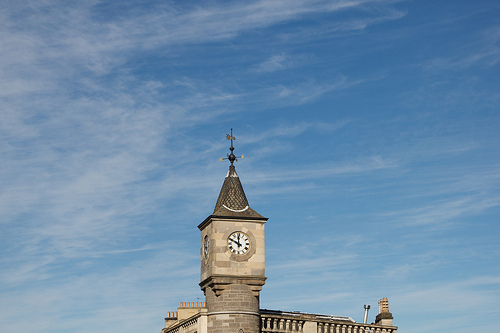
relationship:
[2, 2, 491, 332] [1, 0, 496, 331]
clouds in sky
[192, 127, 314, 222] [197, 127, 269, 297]
vane on steeple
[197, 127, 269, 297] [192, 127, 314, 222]
steeple has vane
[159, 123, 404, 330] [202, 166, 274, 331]
building with tower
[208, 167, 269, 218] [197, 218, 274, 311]
pointed roof for clock tower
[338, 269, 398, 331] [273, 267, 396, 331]
object from roof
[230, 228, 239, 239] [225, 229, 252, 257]
numeral on clock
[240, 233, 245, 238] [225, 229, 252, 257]
numeral on clock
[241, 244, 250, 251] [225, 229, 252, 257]
numeral on clock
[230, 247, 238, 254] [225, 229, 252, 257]
numeral on clock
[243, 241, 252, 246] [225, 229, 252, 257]
numeral on clock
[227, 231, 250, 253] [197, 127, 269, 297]
clock on steeple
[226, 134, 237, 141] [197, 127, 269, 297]
vane on top of steeple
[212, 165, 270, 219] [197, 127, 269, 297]
pointed roof on top of steeple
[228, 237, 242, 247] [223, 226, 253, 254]
black hand on clock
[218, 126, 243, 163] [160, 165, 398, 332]
weather vane on roof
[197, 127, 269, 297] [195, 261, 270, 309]
steeple made of brick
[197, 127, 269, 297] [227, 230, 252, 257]
steeple has clock face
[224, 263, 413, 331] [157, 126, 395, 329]
balcony on top church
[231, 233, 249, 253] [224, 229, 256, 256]
numerals on clock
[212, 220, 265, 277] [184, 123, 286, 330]
bricks on tower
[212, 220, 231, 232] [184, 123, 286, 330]
bricks on tower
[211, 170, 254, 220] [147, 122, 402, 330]
steeple on castle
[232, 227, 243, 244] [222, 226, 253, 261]
black hand on clock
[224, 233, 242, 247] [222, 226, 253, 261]
black hand on clock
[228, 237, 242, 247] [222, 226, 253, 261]
black hand on clock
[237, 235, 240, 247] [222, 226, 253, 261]
black hand on clock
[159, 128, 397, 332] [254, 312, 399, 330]
building has rail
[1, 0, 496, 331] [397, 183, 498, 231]
sky has cloud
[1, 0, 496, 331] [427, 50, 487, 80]
sky has cloud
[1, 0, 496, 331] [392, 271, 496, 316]
sky has cloud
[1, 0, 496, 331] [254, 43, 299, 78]
sky has cloud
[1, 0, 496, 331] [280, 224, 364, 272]
sky has cloud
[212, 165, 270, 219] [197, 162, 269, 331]
pointed roof on tower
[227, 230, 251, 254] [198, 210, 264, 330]
clock on tower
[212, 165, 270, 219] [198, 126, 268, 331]
pointed roof on steeple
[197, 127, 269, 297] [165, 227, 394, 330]
steeple on building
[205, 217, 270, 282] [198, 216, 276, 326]
clock on steeple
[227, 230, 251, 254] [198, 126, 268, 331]
clock on steeple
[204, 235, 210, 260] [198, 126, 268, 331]
clock on steeple